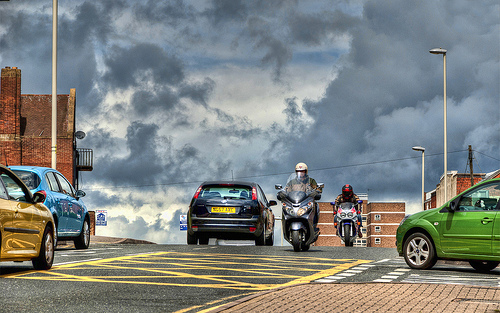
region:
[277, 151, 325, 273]
PErson riding a motorcycle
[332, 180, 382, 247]
PErson riding a motorcycle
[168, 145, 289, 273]
Car driving on road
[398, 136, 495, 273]
Car driving on road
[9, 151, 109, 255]
Car driving on road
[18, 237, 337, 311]
Yellow line on pavement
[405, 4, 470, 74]
White clouds in the sky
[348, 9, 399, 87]
White clouds in the sky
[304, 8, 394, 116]
White clouds in the sky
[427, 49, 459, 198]
a tall gray light pole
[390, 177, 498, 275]
part of a green car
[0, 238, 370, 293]
a large yellow street marking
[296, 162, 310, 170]
a white bike helmet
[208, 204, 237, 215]
a yellow license plate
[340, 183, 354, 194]
a red and black helmet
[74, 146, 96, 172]
a black balcony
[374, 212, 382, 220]
a window of a building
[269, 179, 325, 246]
a black motorcycle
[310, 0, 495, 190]
a large white cloud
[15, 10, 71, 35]
White clouds in the sky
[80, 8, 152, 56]
White clouds in the sky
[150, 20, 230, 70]
White clouds in the sky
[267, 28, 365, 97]
White clouds in the sky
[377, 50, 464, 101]
White clouds in the sky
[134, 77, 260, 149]
White clouds in the sky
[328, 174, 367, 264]
Person on a motorcycle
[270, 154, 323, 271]
Person on a motorcycle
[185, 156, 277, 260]
dark Car on pavement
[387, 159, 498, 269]
dark Car on pavement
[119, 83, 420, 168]
THE SKY IS DARK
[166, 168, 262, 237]
the car is black in colour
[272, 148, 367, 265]
two bikes are approaching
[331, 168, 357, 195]
the helmet is red in colour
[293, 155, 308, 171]
the helmet is white in colour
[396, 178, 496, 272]
the vehicle is green in colour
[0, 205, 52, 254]
the vehicle is yellow in colour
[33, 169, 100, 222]
the vehicle is blue in colour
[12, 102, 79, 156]
the wall is brown in colour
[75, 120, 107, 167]
the house has a balcony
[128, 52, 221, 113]
dark clouds in the sky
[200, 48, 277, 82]
blue sky behind clouds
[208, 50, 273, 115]
white clouds in the sky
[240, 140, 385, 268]
bikers on the ground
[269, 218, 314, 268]
front tire of bike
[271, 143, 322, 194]
helmet on the man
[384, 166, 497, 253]
green car on ground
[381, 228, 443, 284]
tire of the car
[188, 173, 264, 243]
back of the car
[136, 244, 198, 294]
yellow lines on ground